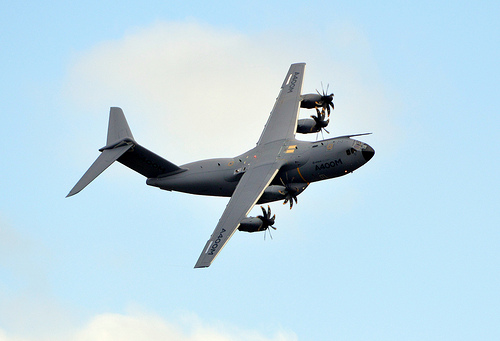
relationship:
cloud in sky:
[68, 17, 393, 200] [2, 1, 495, 335]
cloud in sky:
[75, 303, 311, 339] [2, 1, 495, 335]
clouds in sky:
[106, 207, 175, 276] [2, 1, 495, 335]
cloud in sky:
[68, 17, 393, 200] [377, 1, 498, 339]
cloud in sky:
[75, 303, 311, 339] [377, 1, 498, 339]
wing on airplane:
[195, 162, 281, 265] [63, 61, 375, 271]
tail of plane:
[65, 105, 180, 196] [135, 81, 497, 281]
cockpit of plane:
[342, 139, 362, 158] [65, 62, 375, 268]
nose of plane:
[359, 138, 376, 162] [65, 62, 375, 268]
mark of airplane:
[206, 226, 226, 256] [107, 67, 422, 270]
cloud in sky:
[75, 303, 311, 339] [288, 257, 340, 294]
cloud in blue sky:
[68, 17, 393, 200] [363, 201, 433, 301]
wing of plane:
[193, 162, 283, 270] [65, 62, 375, 268]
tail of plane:
[65, 106, 180, 197] [65, 62, 375, 268]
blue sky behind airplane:
[0, 0, 500, 341] [63, 61, 375, 271]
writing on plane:
[312, 157, 344, 174] [65, 62, 375, 268]